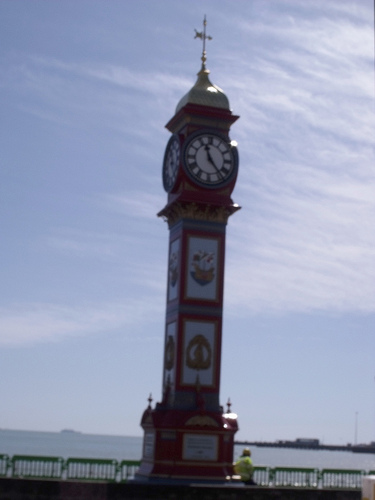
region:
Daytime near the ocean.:
[0, 0, 372, 495]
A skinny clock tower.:
[139, 48, 255, 477]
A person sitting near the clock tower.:
[234, 442, 258, 482]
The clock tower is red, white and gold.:
[138, 55, 246, 482]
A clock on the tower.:
[183, 128, 232, 184]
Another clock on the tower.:
[154, 129, 180, 192]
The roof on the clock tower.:
[169, 64, 236, 106]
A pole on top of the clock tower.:
[189, 12, 215, 75]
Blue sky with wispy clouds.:
[0, 0, 374, 401]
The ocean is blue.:
[16, 433, 118, 453]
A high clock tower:
[154, 102, 242, 217]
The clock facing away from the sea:
[186, 128, 236, 189]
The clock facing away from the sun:
[160, 132, 184, 191]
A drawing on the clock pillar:
[187, 241, 216, 288]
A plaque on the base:
[180, 432, 219, 461]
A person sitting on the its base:
[233, 446, 257, 484]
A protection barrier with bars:
[275, 467, 315, 486]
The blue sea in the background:
[2, 435, 113, 451]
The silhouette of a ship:
[56, 427, 82, 435]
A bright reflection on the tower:
[229, 139, 237, 147]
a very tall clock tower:
[89, 10, 265, 492]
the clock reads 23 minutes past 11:
[188, 111, 253, 209]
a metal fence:
[6, 453, 135, 483]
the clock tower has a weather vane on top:
[186, 8, 227, 91]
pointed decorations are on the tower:
[141, 391, 246, 417]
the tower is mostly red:
[153, 171, 239, 245]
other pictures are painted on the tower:
[181, 226, 230, 442]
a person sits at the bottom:
[231, 448, 271, 491]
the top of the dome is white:
[177, 49, 250, 129]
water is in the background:
[12, 427, 163, 479]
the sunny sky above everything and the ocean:
[3, 3, 371, 442]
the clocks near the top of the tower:
[153, 131, 237, 192]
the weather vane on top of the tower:
[189, 18, 210, 67]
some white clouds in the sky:
[233, 4, 374, 320]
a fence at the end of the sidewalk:
[1, 455, 372, 490]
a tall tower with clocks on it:
[146, 27, 250, 495]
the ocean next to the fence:
[0, 423, 374, 484]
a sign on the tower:
[178, 435, 223, 463]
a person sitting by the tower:
[236, 450, 254, 484]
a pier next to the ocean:
[268, 435, 374, 455]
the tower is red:
[158, 126, 246, 484]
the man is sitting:
[227, 434, 265, 487]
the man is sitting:
[234, 446, 277, 496]